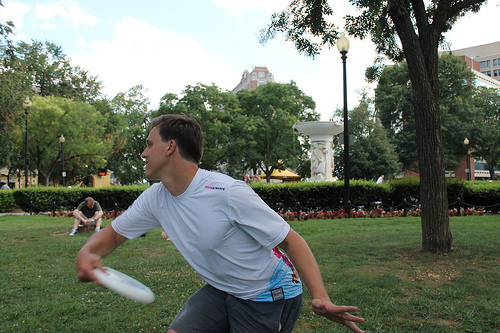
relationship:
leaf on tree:
[28, 60, 106, 132] [6, 30, 98, 191]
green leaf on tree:
[121, 112, 132, 125] [1, 17, 139, 187]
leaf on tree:
[117, 95, 122, 102] [80, 40, 350, 245]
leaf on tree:
[191, 90, 196, 95] [157, 76, 319, 188]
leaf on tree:
[202, 90, 207, 102] [140, 77, 317, 186]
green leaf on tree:
[159, 80, 319, 118] [145, 83, 319, 180]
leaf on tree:
[288, 78, 296, 85] [233, 79, 320, 184]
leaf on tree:
[1, 0, 498, 185] [380, 3, 465, 255]